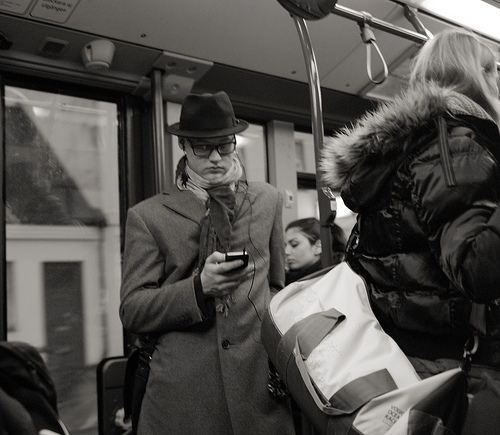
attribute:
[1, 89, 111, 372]
house — white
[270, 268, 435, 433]
bag — large, white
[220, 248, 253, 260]
cellphone — black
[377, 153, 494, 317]
coat — black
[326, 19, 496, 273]
woman — standing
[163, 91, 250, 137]
hat — black, dark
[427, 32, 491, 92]
hair — light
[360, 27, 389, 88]
ring — silver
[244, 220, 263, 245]
wire — black